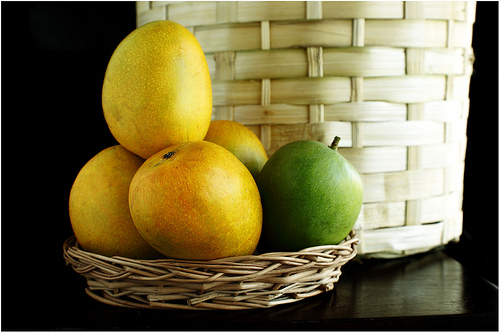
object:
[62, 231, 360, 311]
basket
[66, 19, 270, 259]
four mangos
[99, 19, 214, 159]
mango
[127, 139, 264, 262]
mango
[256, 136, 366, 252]
mango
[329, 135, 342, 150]
stem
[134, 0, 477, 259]
basket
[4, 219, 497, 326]
table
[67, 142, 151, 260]
fruit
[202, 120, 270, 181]
mango